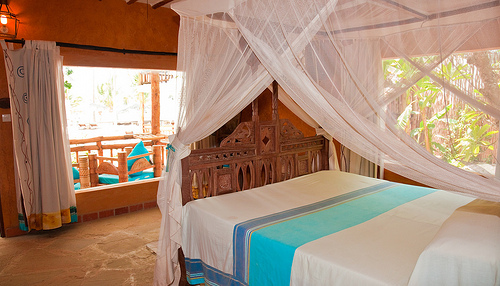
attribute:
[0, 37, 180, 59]
curtain rod — long, black